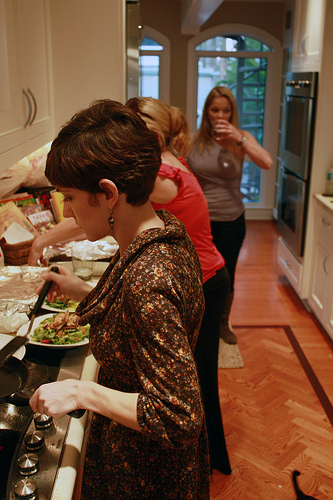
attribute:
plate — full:
[15, 310, 91, 348]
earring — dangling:
[105, 210, 116, 237]